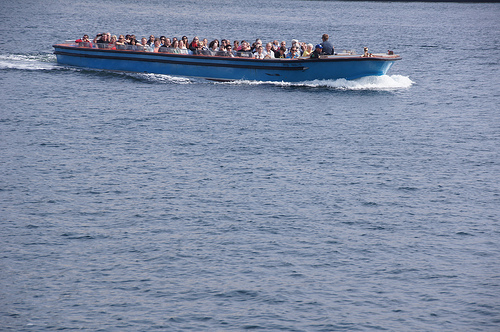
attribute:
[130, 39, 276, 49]
people — sitting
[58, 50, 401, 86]
boat — blue, long, large, floating, white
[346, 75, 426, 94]
water — blue, white, choppy, splashing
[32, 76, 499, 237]
water — pretty, calm, large, blue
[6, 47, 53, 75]
waves — white, small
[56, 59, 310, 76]
line — thick, black, blue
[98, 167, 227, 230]
ripple — small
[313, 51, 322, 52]
hat — blue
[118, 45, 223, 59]
shield — glass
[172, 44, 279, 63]
guard — small, glass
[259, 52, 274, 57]
shirt — white